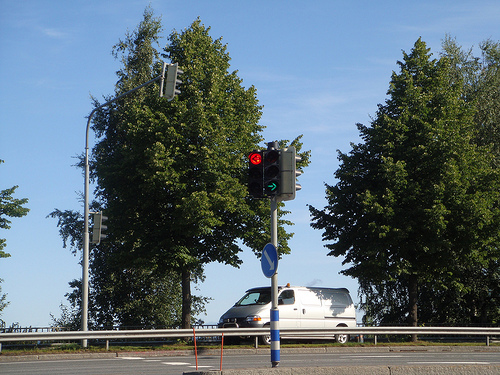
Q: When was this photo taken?
A: During the day.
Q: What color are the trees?
A: Green.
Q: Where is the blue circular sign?
A: On the center pole.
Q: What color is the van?
A: White.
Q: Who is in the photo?
A: No one.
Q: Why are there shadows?
A: The sun is shining.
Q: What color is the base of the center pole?
A: Blue and white.